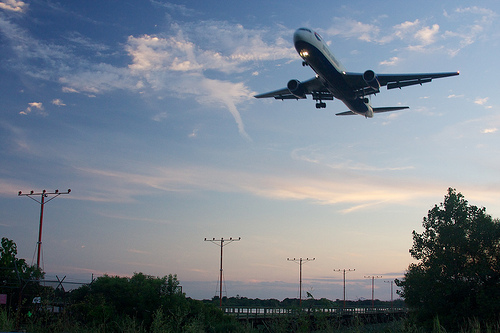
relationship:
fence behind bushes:
[3, 269, 97, 319] [63, 273, 237, 330]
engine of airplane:
[286, 78, 309, 101] [254, 28, 460, 117]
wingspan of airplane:
[253, 70, 462, 101] [254, 28, 460, 117]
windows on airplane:
[319, 42, 342, 66] [254, 28, 460, 117]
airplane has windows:
[254, 28, 460, 117] [319, 42, 342, 66]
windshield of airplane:
[295, 28, 315, 33] [254, 28, 460, 117]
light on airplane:
[300, 48, 309, 58] [254, 28, 460, 117]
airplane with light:
[254, 28, 460, 117] [300, 48, 309, 58]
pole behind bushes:
[205, 234, 241, 296] [63, 273, 237, 330]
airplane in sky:
[254, 28, 460, 117] [0, 1, 499, 301]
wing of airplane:
[347, 68, 463, 90] [254, 28, 460, 117]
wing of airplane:
[254, 76, 330, 101] [254, 28, 460, 117]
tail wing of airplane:
[373, 105, 407, 113] [254, 28, 460, 117]